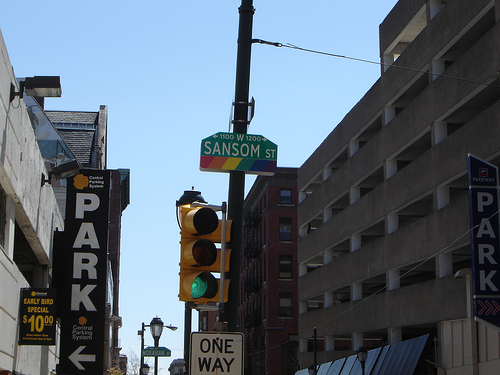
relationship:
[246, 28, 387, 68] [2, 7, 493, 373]
power line across street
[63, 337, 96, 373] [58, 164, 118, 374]
arrow in sign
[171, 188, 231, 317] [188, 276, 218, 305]
traffic sigal in light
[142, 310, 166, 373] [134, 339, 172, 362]
pole has base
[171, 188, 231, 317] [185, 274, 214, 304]
traffic sigal has light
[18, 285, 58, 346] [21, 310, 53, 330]
sign indicating price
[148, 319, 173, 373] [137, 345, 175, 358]
lamp with sign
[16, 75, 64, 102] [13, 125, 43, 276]
light on garage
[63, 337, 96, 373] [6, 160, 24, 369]
arrow pointing toward area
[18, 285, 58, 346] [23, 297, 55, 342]
sign advertising special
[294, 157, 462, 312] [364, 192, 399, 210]
structure built with concrete